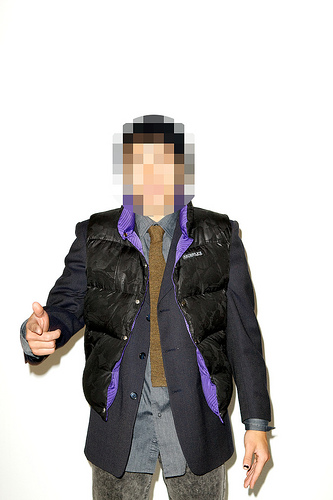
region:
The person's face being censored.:
[103, 106, 197, 215]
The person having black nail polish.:
[240, 429, 265, 495]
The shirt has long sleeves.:
[240, 417, 278, 433]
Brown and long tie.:
[149, 219, 172, 387]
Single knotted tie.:
[143, 222, 166, 241]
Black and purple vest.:
[93, 212, 149, 408]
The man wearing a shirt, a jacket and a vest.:
[36, 205, 271, 416]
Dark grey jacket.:
[171, 366, 194, 468]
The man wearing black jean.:
[166, 475, 221, 496]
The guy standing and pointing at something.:
[14, 110, 294, 498]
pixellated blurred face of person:
[89, 110, 210, 226]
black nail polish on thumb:
[240, 461, 252, 471]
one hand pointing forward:
[8, 302, 63, 367]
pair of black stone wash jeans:
[71, 451, 228, 499]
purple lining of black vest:
[192, 349, 224, 429]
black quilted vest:
[69, 199, 238, 434]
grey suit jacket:
[8, 207, 282, 477]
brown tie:
[139, 222, 185, 398]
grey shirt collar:
[131, 211, 181, 242]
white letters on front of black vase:
[179, 249, 207, 262]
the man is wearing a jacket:
[28, 205, 263, 407]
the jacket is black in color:
[32, 211, 258, 419]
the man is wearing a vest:
[91, 205, 236, 423]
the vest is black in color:
[77, 211, 230, 416]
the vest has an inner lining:
[107, 206, 219, 424]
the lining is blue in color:
[106, 203, 225, 425]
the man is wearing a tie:
[144, 223, 172, 388]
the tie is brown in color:
[140, 220, 168, 382]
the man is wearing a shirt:
[124, 213, 192, 476]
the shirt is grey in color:
[128, 216, 190, 474]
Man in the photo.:
[12, 111, 279, 498]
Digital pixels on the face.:
[104, 113, 199, 218]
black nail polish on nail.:
[242, 462, 249, 470]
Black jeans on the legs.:
[82, 428, 231, 498]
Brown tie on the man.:
[141, 225, 173, 388]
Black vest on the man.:
[66, 198, 237, 430]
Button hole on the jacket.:
[157, 305, 170, 315]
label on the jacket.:
[181, 248, 203, 261]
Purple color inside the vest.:
[99, 199, 225, 423]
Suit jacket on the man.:
[11, 201, 274, 477]